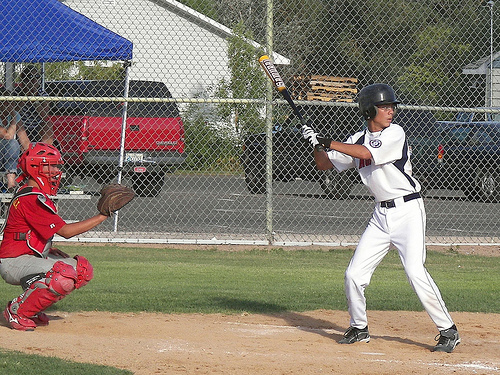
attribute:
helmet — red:
[352, 75, 402, 122]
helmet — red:
[16, 137, 71, 194]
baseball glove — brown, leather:
[99, 185, 131, 213]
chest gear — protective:
[0, 183, 59, 247]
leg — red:
[393, 226, 473, 335]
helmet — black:
[348, 73, 403, 128]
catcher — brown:
[84, 177, 146, 229]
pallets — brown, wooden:
[289, 74, 356, 101]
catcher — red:
[3, 135, 138, 332]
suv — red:
[20, 67, 192, 206]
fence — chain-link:
[1, 2, 498, 244]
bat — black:
[257, 52, 324, 152]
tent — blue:
[0, 9, 145, 82]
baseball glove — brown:
[91, 182, 135, 217]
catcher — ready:
[0, 77, 140, 369]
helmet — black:
[357, 81, 398, 124]